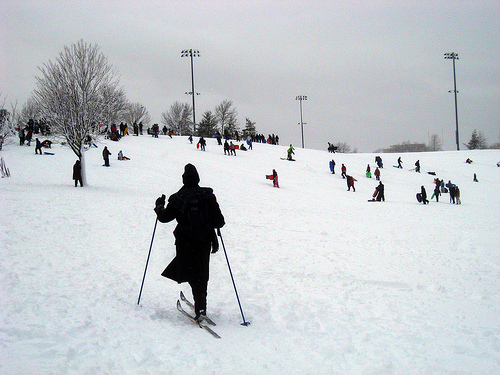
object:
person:
[153, 162, 226, 322]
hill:
[0, 133, 499, 375]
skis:
[176, 298, 222, 338]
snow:
[0, 131, 499, 374]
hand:
[153, 193, 169, 207]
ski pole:
[137, 193, 167, 306]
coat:
[154, 185, 226, 283]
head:
[181, 163, 201, 185]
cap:
[181, 162, 201, 184]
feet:
[193, 312, 204, 321]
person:
[72, 159, 82, 188]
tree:
[29, 38, 132, 186]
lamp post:
[188, 49, 197, 136]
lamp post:
[297, 95, 305, 149]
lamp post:
[450, 50, 460, 151]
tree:
[160, 101, 196, 137]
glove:
[154, 193, 166, 208]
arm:
[155, 192, 178, 224]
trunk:
[79, 155, 88, 187]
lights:
[181, 48, 200, 58]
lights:
[295, 94, 307, 102]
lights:
[443, 51, 458, 60]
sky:
[0, 0, 499, 138]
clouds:
[0, 2, 499, 145]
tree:
[191, 108, 221, 137]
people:
[102, 145, 113, 168]